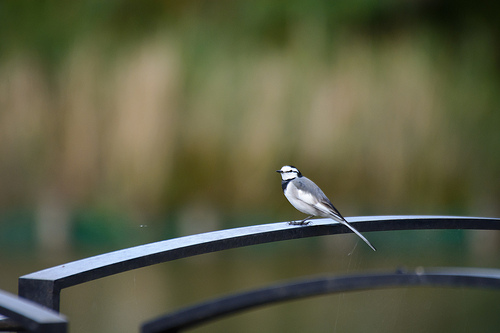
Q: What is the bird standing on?
A: A railing.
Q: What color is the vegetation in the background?
A: Green.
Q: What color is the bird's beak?
A: Black.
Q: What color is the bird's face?
A: Black and white.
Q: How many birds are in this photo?
A: One.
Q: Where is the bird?
A: On a rail.